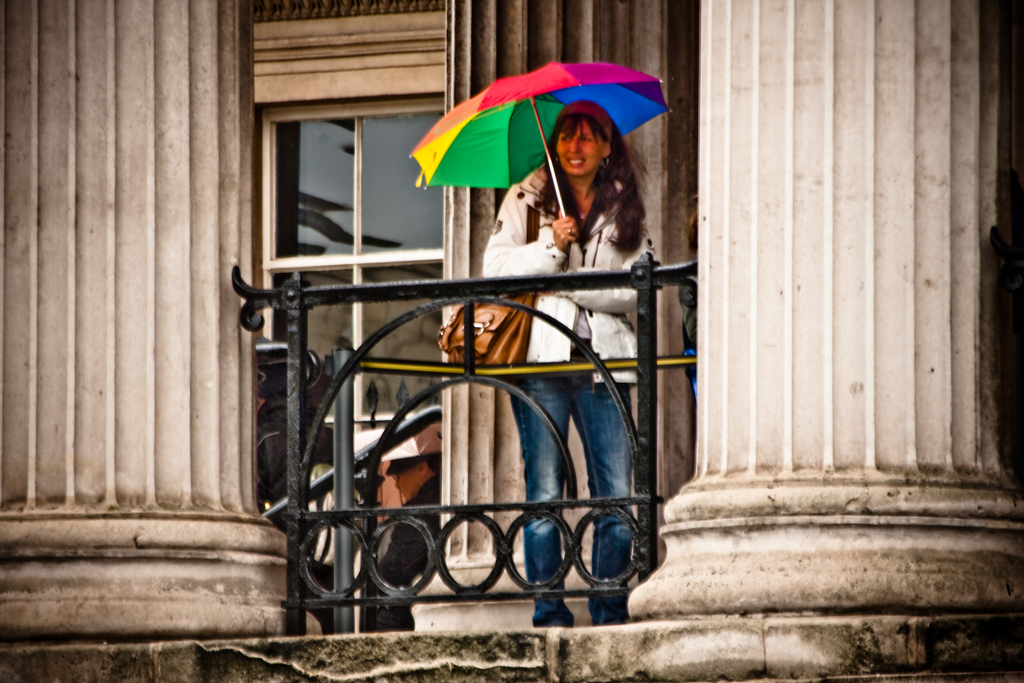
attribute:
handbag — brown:
[440, 285, 544, 379]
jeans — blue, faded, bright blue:
[513, 388, 658, 611]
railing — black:
[217, 245, 708, 624]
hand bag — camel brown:
[445, 273, 534, 364]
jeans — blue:
[501, 344, 646, 610]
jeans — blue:
[500, 396, 661, 615]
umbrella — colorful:
[402, 39, 787, 236]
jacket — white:
[437, 184, 677, 414]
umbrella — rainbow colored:
[366, 31, 695, 222]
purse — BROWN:
[439, 286, 528, 375]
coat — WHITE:
[472, 171, 667, 377]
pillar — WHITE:
[621, 20, 993, 606]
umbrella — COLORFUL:
[404, 50, 672, 197]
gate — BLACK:
[230, 260, 688, 626]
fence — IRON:
[229, 243, 703, 630]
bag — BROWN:
[435, 277, 539, 370]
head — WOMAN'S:
[549, 94, 617, 174]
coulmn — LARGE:
[629, 18, 977, 613]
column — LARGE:
[13, 27, 275, 626]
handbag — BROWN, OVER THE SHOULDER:
[424, 188, 552, 374]